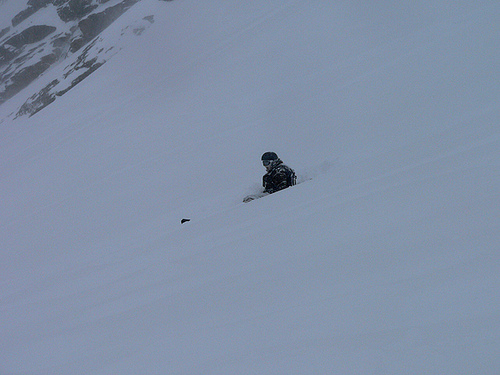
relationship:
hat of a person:
[244, 143, 291, 179] [232, 130, 321, 228]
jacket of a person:
[264, 165, 294, 189] [234, 131, 333, 267]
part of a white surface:
[439, 247, 452, 266] [426, 264, 484, 356]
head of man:
[258, 147, 273, 166] [231, 140, 340, 221]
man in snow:
[178, 148, 300, 227] [122, 51, 444, 296]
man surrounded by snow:
[178, 148, 300, 227] [99, 72, 446, 306]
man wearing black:
[178, 148, 300, 227] [265, 169, 288, 189]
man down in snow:
[178, 148, 300, 227] [98, 108, 412, 333]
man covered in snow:
[178, 148, 300, 227] [200, 38, 448, 338]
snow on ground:
[0, 0, 500, 373] [69, 197, 472, 357]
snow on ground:
[124, 74, 430, 321] [67, 288, 412, 362]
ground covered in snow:
[93, 197, 485, 343] [136, 219, 448, 330]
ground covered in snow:
[1, 0, 500, 373] [87, 219, 418, 362]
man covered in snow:
[235, 135, 338, 222] [129, 252, 444, 363]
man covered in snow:
[231, 140, 323, 226] [96, 220, 440, 340]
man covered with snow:
[178, 148, 300, 227] [96, 220, 440, 340]